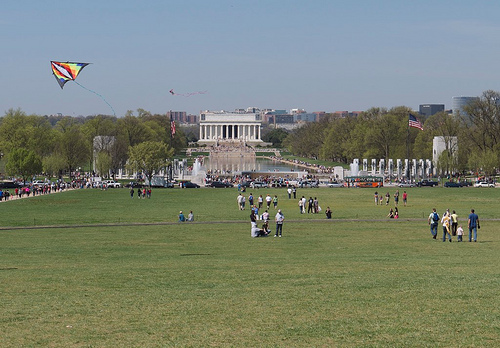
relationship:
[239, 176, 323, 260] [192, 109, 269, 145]
people at building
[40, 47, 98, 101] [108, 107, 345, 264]
kite in park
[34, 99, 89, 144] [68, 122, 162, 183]
trees on side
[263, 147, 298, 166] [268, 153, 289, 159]
pool of water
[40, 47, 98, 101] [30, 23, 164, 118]
kite in air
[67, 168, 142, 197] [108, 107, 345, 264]
bus has park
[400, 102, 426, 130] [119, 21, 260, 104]
flag in sky